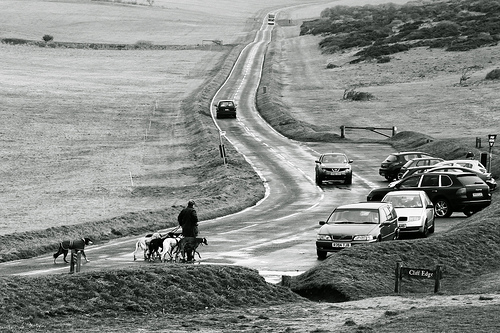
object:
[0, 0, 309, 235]
farmlands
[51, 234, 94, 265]
dog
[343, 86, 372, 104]
trees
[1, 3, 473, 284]
road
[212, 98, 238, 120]
car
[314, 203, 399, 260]
car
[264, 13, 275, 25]
bus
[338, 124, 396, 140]
gate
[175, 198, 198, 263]
man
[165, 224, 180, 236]
leashes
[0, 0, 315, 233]
grass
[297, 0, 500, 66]
brush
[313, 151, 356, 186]
car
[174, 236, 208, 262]
dog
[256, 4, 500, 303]
roadside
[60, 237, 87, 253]
vest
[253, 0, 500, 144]
hills